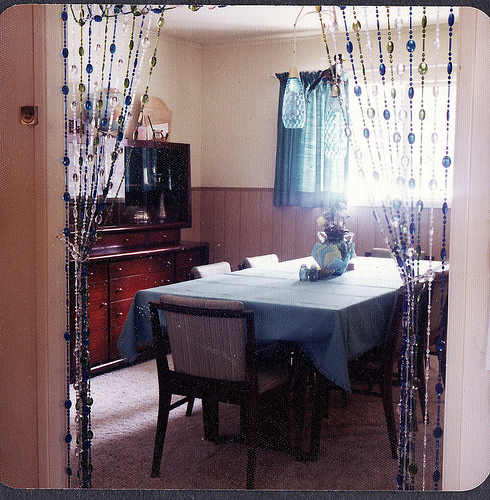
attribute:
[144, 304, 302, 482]
chair — sitting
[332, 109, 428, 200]
window — covered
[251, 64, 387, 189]
curtains — blue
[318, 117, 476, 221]
beads — blue, gold